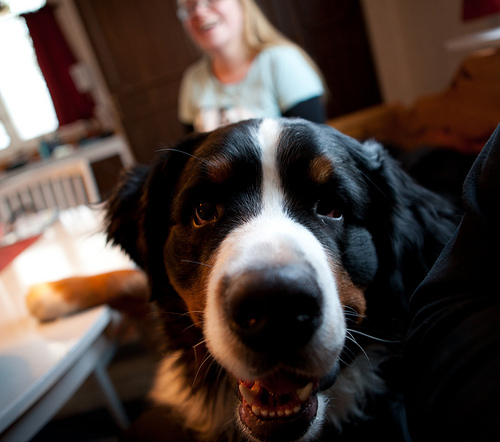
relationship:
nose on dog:
[224, 264, 324, 353] [99, 121, 452, 438]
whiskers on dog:
[331, 304, 396, 376] [99, 121, 452, 438]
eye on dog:
[192, 197, 222, 227] [99, 121, 452, 438]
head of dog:
[153, 116, 390, 440] [99, 121, 452, 438]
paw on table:
[21, 282, 68, 324] [5, 190, 163, 420]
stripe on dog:
[252, 114, 292, 223] [99, 121, 452, 438]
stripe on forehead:
[252, 114, 292, 223] [175, 123, 364, 203]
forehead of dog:
[175, 123, 364, 203] [99, 121, 452, 438]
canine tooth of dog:
[239, 382, 315, 418] [75, 114, 431, 439]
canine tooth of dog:
[239, 382, 315, 418] [78, 131, 456, 412]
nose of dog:
[224, 264, 324, 353] [135, 97, 445, 404]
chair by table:
[2, 153, 104, 232] [0, 207, 146, 439]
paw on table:
[21, 282, 68, 324] [0, 211, 131, 438]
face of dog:
[167, 120, 372, 440] [99, 121, 452, 438]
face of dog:
[167, 120, 372, 440] [75, 114, 431, 439]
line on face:
[253, 113, 285, 211] [167, 120, 372, 440]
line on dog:
[253, 113, 285, 211] [75, 114, 431, 439]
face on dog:
[167, 120, 372, 440] [105, 90, 468, 431]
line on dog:
[253, 113, 285, 211] [105, 90, 468, 431]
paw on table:
[21, 282, 68, 324] [0, 207, 146, 439]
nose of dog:
[224, 264, 324, 353] [99, 121, 452, 438]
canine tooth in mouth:
[239, 382, 315, 418] [212, 347, 341, 437]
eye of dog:
[310, 194, 346, 221] [26, 114, 458, 438]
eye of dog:
[188, 196, 222, 230] [26, 114, 458, 438]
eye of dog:
[192, 197, 222, 227] [45, 111, 467, 426]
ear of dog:
[358, 134, 469, 305] [99, 121, 452, 438]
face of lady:
[174, 0, 244, 49] [175, 0, 330, 132]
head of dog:
[106, 116, 452, 440] [103, 108, 498, 436]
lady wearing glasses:
[175, 6, 329, 131] [174, 4, 196, 20]